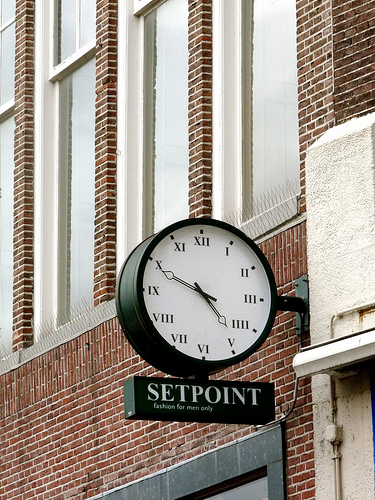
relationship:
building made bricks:
[3, 6, 363, 498] [5, 4, 360, 479]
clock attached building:
[116, 217, 303, 375] [3, 6, 363, 498]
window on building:
[217, 1, 302, 206] [3, 6, 363, 498]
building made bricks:
[3, 6, 363, 498] [93, 93, 115, 294]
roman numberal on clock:
[193, 236, 210, 246] [116, 217, 303, 375]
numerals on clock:
[241, 291, 262, 304] [112, 202, 297, 371]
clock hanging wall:
[120, 216, 301, 367] [3, 4, 363, 496]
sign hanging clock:
[131, 376, 276, 424] [116, 217, 303, 375]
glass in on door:
[200, 462, 282, 497] [86, 432, 302, 498]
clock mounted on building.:
[116, 217, 303, 375] [3, 2, 363, 493]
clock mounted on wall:
[116, 217, 303, 375] [0, 219, 312, 497]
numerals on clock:
[149, 238, 258, 351] [117, 230, 285, 361]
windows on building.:
[210, 12, 309, 183] [3, 2, 363, 493]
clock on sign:
[116, 217, 303, 375] [131, 376, 276, 424]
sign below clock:
[119, 372, 276, 420] [116, 217, 303, 375]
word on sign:
[200, 403, 214, 414] [119, 372, 276, 420]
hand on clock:
[162, 270, 217, 301] [116, 217, 303, 375]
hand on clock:
[193, 281, 228, 328] [116, 217, 303, 375]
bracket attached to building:
[215, 277, 284, 331] [257, 2, 369, 477]